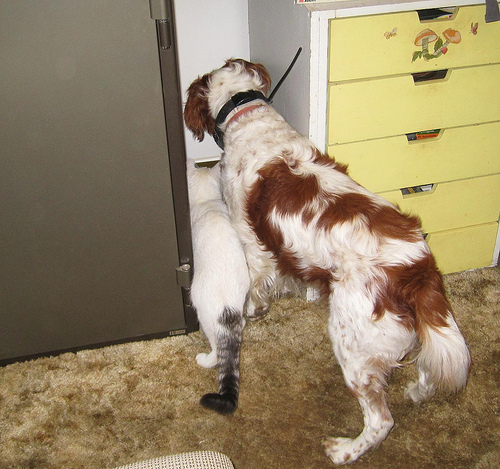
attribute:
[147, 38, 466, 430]
dog — curious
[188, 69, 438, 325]
dog — curious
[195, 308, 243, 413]
tail — brown, black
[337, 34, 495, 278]
drawers — yellow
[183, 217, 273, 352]
cat — white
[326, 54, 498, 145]
drawer — yellow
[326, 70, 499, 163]
drawers — yellow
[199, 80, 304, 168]
dog — curious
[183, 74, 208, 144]
ear — curious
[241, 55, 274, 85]
ear — curious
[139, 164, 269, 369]
cat — small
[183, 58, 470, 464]
dog — medium-sized, white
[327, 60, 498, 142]
drawer — yellow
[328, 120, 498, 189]
drawer — yellow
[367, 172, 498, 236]
drawer — yellow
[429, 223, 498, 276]
drawer — yellow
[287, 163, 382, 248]
fur — brown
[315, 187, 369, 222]
spot — brown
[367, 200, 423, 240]
spot — brown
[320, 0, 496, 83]
drawer — yellow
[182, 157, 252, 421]
cat — white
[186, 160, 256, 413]
cat — small, white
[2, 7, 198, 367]
door — grey